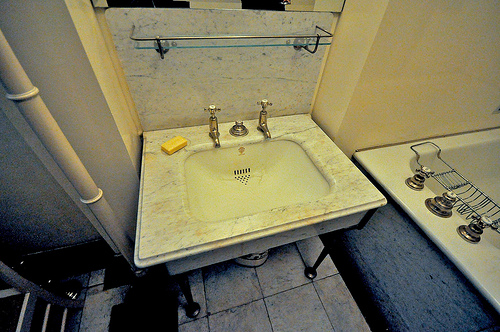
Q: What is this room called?
A: Bathroom.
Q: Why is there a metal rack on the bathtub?
A: To store bath items.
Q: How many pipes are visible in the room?
A: 1.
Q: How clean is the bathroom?
A: Fairly clean.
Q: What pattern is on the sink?
A: Marble.